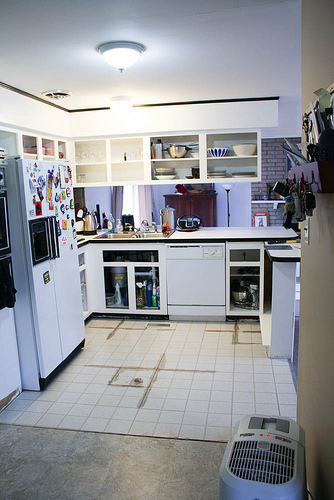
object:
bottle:
[105, 282, 128, 306]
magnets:
[25, 159, 77, 251]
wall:
[249, 34, 333, 231]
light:
[96, 38, 146, 75]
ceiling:
[0, 0, 302, 139]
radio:
[175, 213, 202, 231]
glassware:
[75, 141, 105, 164]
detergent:
[107, 211, 115, 233]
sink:
[91, 228, 175, 241]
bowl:
[232, 144, 257, 157]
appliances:
[151, 135, 199, 159]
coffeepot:
[82, 211, 97, 235]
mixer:
[231, 279, 259, 311]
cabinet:
[224, 237, 265, 318]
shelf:
[225, 243, 264, 319]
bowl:
[161, 143, 193, 158]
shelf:
[150, 154, 199, 162]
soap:
[114, 282, 122, 304]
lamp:
[220, 183, 235, 226]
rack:
[273, 169, 333, 230]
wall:
[296, 211, 333, 498]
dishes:
[154, 166, 178, 180]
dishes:
[207, 169, 256, 179]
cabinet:
[144, 127, 200, 184]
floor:
[0, 320, 299, 499]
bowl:
[207, 147, 230, 157]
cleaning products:
[135, 280, 160, 309]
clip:
[47, 168, 55, 180]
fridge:
[4, 159, 86, 392]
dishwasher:
[165, 242, 226, 323]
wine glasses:
[76, 144, 106, 164]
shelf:
[75, 138, 107, 164]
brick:
[251, 135, 306, 226]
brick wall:
[250, 135, 302, 228]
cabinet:
[206, 133, 262, 178]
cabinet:
[102, 248, 160, 311]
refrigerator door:
[19, 161, 86, 378]